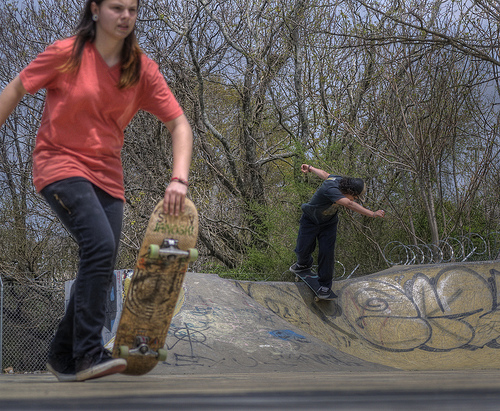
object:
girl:
[1, 0, 202, 387]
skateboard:
[111, 195, 202, 377]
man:
[287, 162, 386, 303]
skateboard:
[287, 262, 339, 305]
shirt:
[17, 37, 185, 195]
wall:
[63, 262, 500, 378]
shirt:
[301, 174, 346, 224]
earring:
[92, 14, 100, 22]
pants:
[38, 179, 127, 358]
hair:
[56, 0, 143, 90]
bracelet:
[170, 176, 189, 187]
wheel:
[148, 243, 160, 259]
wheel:
[187, 246, 198, 262]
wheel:
[117, 346, 129, 359]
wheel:
[155, 348, 169, 362]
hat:
[338, 174, 367, 202]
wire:
[382, 241, 408, 266]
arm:
[309, 165, 332, 178]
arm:
[328, 188, 374, 218]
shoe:
[45, 355, 78, 382]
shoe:
[72, 350, 129, 382]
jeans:
[294, 217, 337, 287]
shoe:
[289, 261, 314, 272]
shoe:
[316, 284, 333, 300]